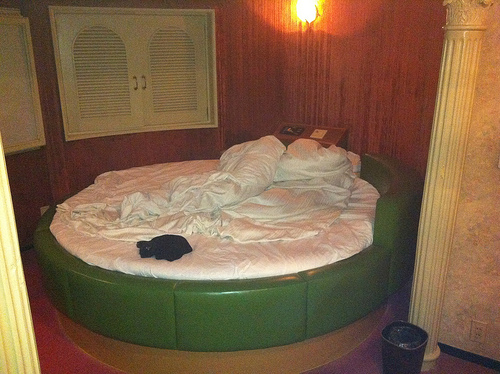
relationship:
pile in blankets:
[62, 141, 351, 228] [49, 137, 382, 283]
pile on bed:
[62, 141, 351, 228] [35, 121, 418, 373]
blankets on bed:
[49, 137, 382, 283] [35, 121, 418, 373]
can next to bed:
[380, 317, 429, 373] [35, 121, 418, 373]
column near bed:
[0, 126, 42, 372] [35, 121, 418, 373]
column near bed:
[404, 0, 489, 362] [35, 121, 418, 373]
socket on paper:
[468, 318, 486, 347] [425, 2, 499, 363]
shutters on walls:
[52, 9, 215, 137] [0, 1, 446, 251]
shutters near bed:
[52, 9, 215, 137] [35, 121, 418, 373]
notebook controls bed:
[310, 127, 328, 140] [35, 121, 418, 373]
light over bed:
[294, 1, 321, 28] [35, 121, 418, 373]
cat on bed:
[133, 233, 192, 261] [35, 121, 418, 373]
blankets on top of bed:
[49, 137, 382, 283] [35, 121, 418, 373]